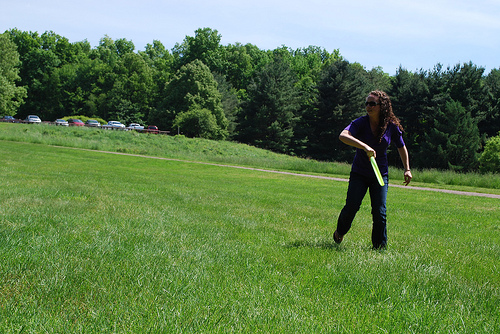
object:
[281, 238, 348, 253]
shadow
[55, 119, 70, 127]
cars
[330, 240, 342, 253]
sandals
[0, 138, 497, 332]
grass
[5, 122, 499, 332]
ground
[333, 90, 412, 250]
woman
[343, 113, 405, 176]
purple shirt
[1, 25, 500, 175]
field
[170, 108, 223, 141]
trees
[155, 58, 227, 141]
tree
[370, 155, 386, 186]
frisbee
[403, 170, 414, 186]
hand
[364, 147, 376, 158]
hand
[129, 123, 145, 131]
car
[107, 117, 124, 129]
car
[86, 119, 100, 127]
car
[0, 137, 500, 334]
field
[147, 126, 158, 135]
car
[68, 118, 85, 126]
car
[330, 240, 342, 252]
foot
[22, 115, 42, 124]
car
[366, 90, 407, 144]
hair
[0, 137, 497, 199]
path